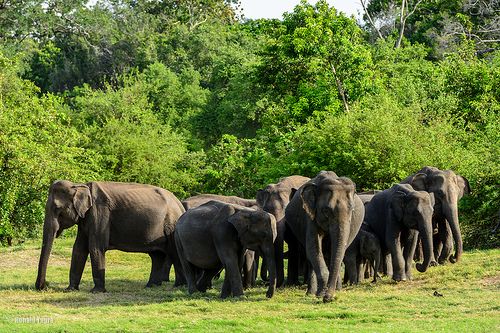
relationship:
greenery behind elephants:
[0, 0, 499, 246] [35, 165, 472, 304]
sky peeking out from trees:
[228, 0, 372, 27] [0, 0, 499, 246]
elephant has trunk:
[174, 200, 277, 299] [259, 244, 279, 300]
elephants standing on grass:
[35, 165, 472, 304] [1, 234, 499, 332]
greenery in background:
[0, 0, 499, 246] [0, 1, 499, 251]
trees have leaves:
[0, 0, 499, 246] [0, 1, 499, 252]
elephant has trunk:
[36, 178, 187, 293] [34, 224, 59, 291]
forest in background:
[0, 0, 499, 246] [0, 1, 499, 251]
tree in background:
[251, 1, 398, 112] [0, 1, 499, 251]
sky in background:
[228, 0, 372, 27] [0, 1, 499, 251]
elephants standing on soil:
[35, 165, 472, 304] [1, 234, 500, 331]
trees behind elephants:
[0, 0, 499, 246] [35, 165, 472, 304]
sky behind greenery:
[228, 0, 372, 27] [0, 0, 499, 246]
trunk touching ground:
[34, 224, 59, 291] [1, 234, 499, 332]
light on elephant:
[267, 211, 278, 246] [174, 200, 277, 299]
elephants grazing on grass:
[35, 165, 472, 304] [1, 234, 499, 332]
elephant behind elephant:
[180, 192, 256, 212] [174, 200, 277, 299]